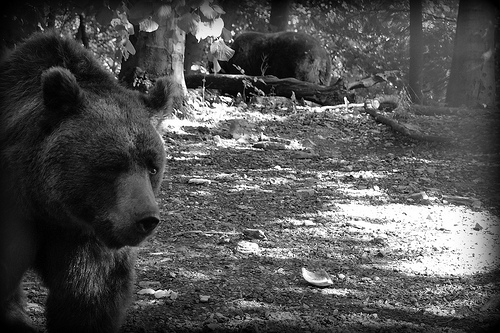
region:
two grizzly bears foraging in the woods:
[0, 0, 497, 331]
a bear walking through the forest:
[2, 31, 179, 332]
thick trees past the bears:
[332, 1, 416, 101]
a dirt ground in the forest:
[167, 121, 497, 331]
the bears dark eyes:
[147, 162, 157, 179]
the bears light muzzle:
[103, 175, 160, 250]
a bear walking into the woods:
[228, 29, 332, 101]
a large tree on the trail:
[118, 0, 232, 87]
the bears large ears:
[38, 65, 87, 127]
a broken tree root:
[363, 96, 498, 155]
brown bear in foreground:
[6, 28, 186, 331]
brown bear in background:
[226, 19, 361, 99]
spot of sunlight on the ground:
[332, 181, 499, 291]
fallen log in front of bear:
[184, 61, 361, 111]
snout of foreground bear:
[107, 178, 178, 258]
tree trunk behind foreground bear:
[117, 3, 202, 114]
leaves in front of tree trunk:
[105, 3, 225, 61]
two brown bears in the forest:
[2, 12, 354, 329]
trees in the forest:
[3, 0, 499, 149]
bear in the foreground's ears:
[35, 63, 173, 115]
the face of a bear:
[42, 71, 171, 248]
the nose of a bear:
[134, 213, 160, 233]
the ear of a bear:
[37, 65, 86, 120]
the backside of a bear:
[221, 33, 331, 98]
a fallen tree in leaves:
[182, 76, 384, 113]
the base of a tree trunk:
[122, 0, 191, 105]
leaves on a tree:
[181, 4, 231, 72]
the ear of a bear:
[144, 79, 174, 124]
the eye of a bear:
[142, 162, 159, 177]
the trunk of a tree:
[447, 0, 498, 107]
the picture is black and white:
[38, 21, 480, 313]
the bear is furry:
[0, 22, 219, 297]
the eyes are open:
[83, 132, 173, 187]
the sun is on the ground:
[302, 158, 489, 311]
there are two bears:
[12, 17, 394, 302]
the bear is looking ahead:
[2, 40, 209, 322]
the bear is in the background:
[191, 12, 340, 111]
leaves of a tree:
[85, 2, 235, 62]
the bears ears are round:
[32, 57, 182, 122]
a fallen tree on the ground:
[175, 53, 368, 112]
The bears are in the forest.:
[7, 22, 402, 332]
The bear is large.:
[6, 21, 171, 329]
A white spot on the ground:
[285, 155, 495, 294]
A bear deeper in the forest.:
[214, 22, 371, 121]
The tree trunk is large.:
[131, 10, 216, 130]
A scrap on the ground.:
[299, 250, 349, 307]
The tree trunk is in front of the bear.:
[163, 64, 422, 136]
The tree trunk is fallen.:
[148, 57, 379, 118]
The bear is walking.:
[20, 7, 212, 329]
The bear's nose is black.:
[122, 195, 173, 237]